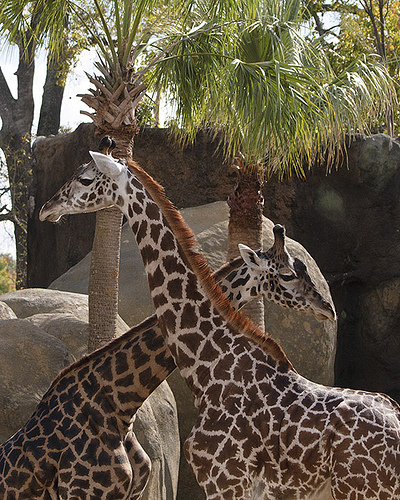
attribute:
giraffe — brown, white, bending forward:
[38, 136, 399, 497]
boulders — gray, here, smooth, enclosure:
[27, 119, 397, 394]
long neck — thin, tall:
[119, 156, 231, 387]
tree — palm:
[144, 12, 384, 330]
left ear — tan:
[87, 149, 123, 178]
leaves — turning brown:
[278, 51, 396, 171]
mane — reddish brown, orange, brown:
[122, 154, 297, 375]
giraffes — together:
[2, 132, 399, 496]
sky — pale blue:
[5, 15, 391, 135]